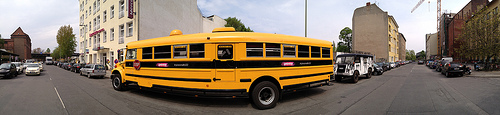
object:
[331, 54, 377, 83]
jeep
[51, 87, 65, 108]
stripe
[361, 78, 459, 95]
road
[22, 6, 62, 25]
clouds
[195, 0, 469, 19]
sky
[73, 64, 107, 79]
van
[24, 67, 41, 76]
car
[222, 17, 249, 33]
tree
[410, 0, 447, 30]
crane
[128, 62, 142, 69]
stop sign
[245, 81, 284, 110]
tire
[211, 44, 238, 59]
window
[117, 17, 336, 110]
bus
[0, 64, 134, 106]
street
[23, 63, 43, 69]
cars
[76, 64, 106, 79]
minivan